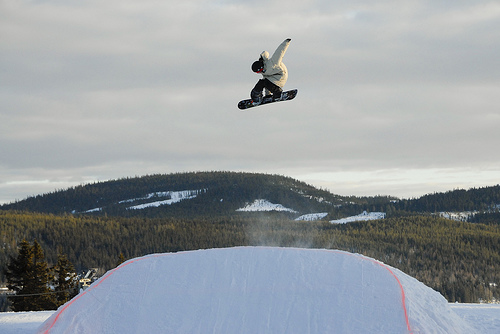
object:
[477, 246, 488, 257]
leaf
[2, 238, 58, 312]
plant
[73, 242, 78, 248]
leaf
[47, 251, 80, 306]
plant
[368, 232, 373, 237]
leaf